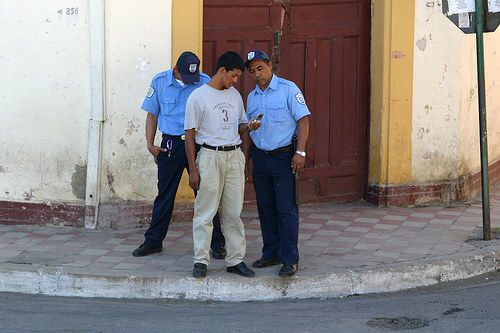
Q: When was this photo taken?
A: Daytime.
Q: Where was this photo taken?
A: On the street.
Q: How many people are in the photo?
A: Three.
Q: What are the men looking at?
A: A cell phone.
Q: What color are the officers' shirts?
A: Blue.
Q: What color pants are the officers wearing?
A: Blue.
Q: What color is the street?
A: Grey.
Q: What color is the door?
A: Red.